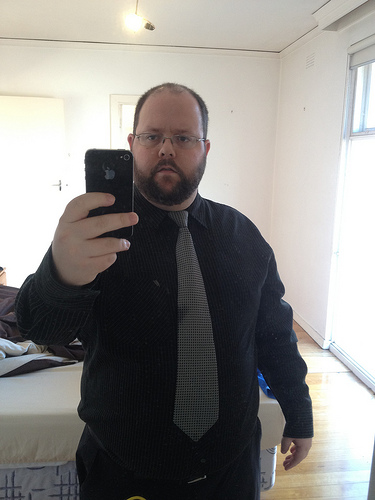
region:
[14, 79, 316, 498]
man taking selfie with phone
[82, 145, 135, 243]
man holding black iphone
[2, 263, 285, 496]
bed behind man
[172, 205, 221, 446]
man wearing grey checkered tie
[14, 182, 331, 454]
man wearing black shirt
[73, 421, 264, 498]
man wearing black pants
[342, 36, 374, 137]
open window to right of man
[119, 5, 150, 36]
yellow light on ceiling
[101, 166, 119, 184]
silver apple logo on back of phone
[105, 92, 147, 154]
door behind man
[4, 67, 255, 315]
"A man taking a selfie"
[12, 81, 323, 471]
"He's wearing a black dress shirt"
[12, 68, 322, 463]
"A guy in a tie"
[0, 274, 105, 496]
"A messy, unmade bed"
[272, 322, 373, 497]
"It's a wood floor"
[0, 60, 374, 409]
"The windows let in a lot of light"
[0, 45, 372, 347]
"The room is really bright"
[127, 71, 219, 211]
"The man wears glasses"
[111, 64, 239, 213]
"The man has a beard"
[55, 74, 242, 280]
"The man uses his camera phone"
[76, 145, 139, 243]
a black iphone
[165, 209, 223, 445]
a checkered tie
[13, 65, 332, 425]
a man wearing black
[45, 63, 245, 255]
a man taking a selfie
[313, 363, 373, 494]
a hardwood floor with light shining on it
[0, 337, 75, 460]
an unmade bed with comforter folded over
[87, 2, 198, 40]
light that is turned on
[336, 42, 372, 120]
an open window in a room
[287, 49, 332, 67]
a vent in the wall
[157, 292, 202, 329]
a stain on a tie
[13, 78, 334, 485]
man holding cell phone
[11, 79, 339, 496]
man in black shirt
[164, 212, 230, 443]
grey and black tie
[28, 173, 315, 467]
black striped button up shirt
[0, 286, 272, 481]
unmade bed with white sheets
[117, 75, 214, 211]
man wearing rimless glasses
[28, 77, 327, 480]
balding man with beard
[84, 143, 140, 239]
black apple phone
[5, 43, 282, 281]
white wall behind man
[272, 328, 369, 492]
brown wooden floor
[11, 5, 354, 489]
a man standing in bedroom is taking a selfie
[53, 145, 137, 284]
a hand is holding a black cell phone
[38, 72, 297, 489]
the man is wearing a gray tie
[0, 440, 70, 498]
a bed is sitting on a wood floor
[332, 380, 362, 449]
light is reflecting on shiny wood floor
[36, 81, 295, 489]
the man is dressed in a black shirt and black pants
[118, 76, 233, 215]
the man is wearing glasses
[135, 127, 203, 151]
the glasses have two lenses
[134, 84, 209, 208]
the man's face has a beard and a moustache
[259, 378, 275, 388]
a blue cover is on the bed